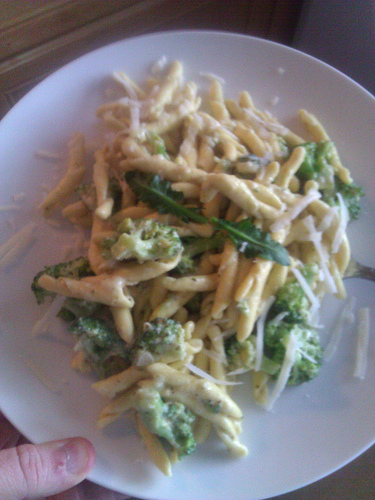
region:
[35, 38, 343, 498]
a plate of food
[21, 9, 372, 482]
a white plate of food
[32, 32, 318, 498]
noodles on a plate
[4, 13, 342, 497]
noodles on a white plate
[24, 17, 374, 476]
a plate with noodles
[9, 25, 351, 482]
a white plate with noodles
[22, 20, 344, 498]
cooked noodles on a plate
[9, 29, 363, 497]
cooked noodles on a white plate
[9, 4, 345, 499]
plate with cooked noodles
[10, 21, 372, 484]
white plate with cooked noodles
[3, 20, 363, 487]
white plate with food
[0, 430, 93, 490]
thumb on edge of plate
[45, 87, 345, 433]
pasta covered in creamy sauce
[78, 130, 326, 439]
broccoli pieces mixed with tubular pasta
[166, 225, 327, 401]
white shredded cheese over meal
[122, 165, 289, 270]
two leaves garnishing entree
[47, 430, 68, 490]
broken skin on thumb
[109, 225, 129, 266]
rectangular cut end of broccoli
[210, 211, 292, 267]
stem through narrow and curly leaf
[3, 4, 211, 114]
wood molding behind plate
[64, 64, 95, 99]
part of a plate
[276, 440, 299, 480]
part of a plate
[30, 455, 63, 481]
part of a finger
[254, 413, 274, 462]
part of a plate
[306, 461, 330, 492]
edge of a plate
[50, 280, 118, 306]
noodle on the plate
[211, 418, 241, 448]
noodle on the plate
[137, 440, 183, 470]
noodle on the plate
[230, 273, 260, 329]
noodle on the plate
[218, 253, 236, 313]
noodle on the plate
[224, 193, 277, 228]
noodle on the plate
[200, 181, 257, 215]
noodle on the plate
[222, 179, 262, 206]
noodle on the plate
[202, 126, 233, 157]
noodle on the plate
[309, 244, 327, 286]
noodle on the plate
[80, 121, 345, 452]
creamy pasta is the food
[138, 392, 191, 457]
broccoli next to pasta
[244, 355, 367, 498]
plate holding food is white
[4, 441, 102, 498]
finger of person touching plate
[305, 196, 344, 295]
cheese on the food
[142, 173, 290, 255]
green garnish on top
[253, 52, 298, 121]
pieces of chesse on plate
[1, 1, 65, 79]
wood cabinet in back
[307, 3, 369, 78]
wall is behind the plate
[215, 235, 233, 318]
pasta is long shaped